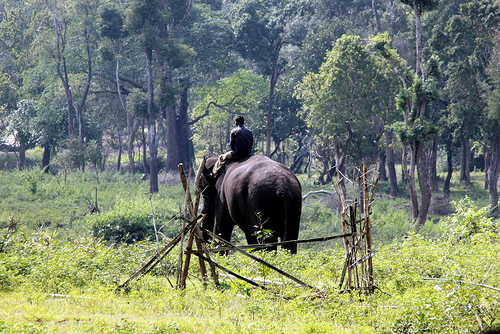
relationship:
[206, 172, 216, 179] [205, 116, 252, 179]
foot of a man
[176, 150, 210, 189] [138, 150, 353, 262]
ear on elephant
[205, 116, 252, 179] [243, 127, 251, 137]
man has shoulder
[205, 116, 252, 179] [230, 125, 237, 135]
man has shoulder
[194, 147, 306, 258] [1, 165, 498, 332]
elephant in field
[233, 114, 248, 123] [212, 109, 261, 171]
head on man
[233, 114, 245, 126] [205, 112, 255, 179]
head on man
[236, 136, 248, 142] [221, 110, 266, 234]
back on man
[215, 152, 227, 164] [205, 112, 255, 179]
knee on man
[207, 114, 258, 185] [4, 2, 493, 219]
person in forest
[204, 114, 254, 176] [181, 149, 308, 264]
person on elephant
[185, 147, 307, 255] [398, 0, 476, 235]
elephant by trees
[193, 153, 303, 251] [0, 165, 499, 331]
elephant in weeds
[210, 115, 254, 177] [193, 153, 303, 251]
person on elephant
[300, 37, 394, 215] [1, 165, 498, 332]
tree in field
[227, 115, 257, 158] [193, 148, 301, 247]
man riding animal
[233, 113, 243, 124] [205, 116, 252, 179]
hair on a man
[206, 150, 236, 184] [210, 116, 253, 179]
leg of a man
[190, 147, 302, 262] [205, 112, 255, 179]
arm of a man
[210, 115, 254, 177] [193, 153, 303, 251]
person on an elephant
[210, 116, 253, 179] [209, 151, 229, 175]
man wearing pants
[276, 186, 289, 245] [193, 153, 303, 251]
tail of elephant